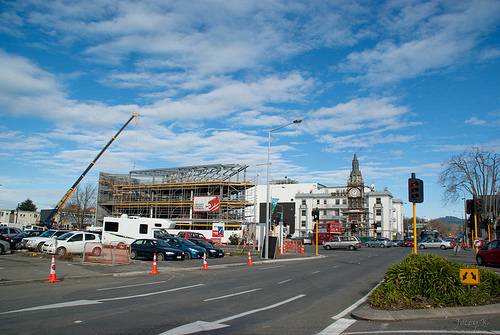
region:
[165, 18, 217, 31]
clouds in the sky.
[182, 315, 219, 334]
white arrow on road.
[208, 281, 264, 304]
white line on road.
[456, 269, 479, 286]
sign in the bushes.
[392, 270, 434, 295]
bushes near the road.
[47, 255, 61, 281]
cone near the curb.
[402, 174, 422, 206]
traffic light on sign.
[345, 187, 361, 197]
clock on the tower.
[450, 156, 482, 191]
limbs on the tree.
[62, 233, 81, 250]
white car in parking lot.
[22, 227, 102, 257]
cars in a parking lot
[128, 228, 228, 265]
cars in a parking lot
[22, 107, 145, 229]
a construction crane at a building site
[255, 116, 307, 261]
a pole light on the side of the street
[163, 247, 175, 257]
the head light of a car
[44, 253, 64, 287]
a caution cone on the side of a street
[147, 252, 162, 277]
a caution cone on the side of a street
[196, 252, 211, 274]
a caution cone on the side of a street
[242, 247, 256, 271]
a caution cone on the side of a street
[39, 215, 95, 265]
THIS IS A CAR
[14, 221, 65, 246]
THIS IS A CAR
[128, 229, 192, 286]
THIS IS A CAR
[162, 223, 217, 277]
THIS IS A CAR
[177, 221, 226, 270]
THIS IS A CAR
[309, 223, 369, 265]
THIS IS A CAR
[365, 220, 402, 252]
THIS IS A CAR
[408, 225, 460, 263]
THIS IS A CAR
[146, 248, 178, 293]
this is a sign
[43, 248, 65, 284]
Safety cone on the street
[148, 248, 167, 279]
Safety cone on the street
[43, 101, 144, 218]
Crane in the background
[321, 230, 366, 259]
Van on the road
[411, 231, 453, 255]
Car on the road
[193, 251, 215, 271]
Safety cone on the road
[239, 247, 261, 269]
Safety cone on the road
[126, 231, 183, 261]
Car parked in lot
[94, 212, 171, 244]
RV parked in lot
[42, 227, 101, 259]
White car parked in lot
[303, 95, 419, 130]
a section of white clouds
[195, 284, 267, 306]
a long white line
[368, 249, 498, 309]
a section of green grass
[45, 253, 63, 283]
a tall orange and white cone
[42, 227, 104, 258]
a small white car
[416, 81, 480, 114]
part of a blue sky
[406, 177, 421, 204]
a black traffic light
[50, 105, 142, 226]
a large crane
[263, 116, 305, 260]
a tall gray light pole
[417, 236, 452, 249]
part of a gray car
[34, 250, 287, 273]
Cones on the side of road.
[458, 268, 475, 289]
Yellow sign in the grass.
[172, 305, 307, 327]
A white arrow painted on the road.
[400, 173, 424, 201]
The traffic signal is red.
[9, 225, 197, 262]
Cars parked in the lot.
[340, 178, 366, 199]
Clock on the building.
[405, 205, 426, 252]
The pole is yellow.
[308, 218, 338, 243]
The bus is red.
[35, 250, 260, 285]
Line of four traffic cones in street.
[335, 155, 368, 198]
Spire topping clock tower.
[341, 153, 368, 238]
Gray building with clock tower.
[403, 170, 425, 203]
Traffic signal lit red.